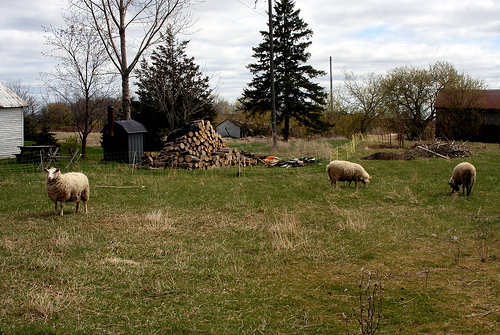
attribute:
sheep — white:
[326, 159, 372, 194]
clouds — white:
[3, 0, 495, 120]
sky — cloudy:
[0, 3, 498, 111]